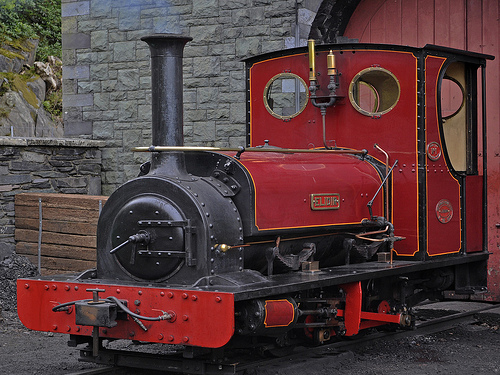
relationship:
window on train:
[267, 75, 308, 115] [16, 34, 496, 373]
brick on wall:
[189, 56, 221, 74] [39, 3, 291, 226]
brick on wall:
[82, 106, 107, 121] [55, 2, 322, 156]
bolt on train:
[214, 297, 221, 303] [16, 34, 496, 373]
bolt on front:
[179, 311, 189, 323] [18, 279, 234, 347]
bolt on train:
[214, 295, 220, 305] [16, 34, 496, 373]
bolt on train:
[190, 294, 196, 301] [16, 34, 496, 373]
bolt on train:
[181, 292, 188, 300] [16, 34, 496, 373]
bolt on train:
[180, 336, 189, 343] [16, 34, 496, 373]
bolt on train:
[168, 334, 176, 344] [16, 34, 496, 373]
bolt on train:
[167, 290, 174, 298] [16, 34, 496, 373]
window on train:
[262, 71, 309, 118] [16, 34, 496, 373]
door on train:
[416, 45, 486, 256] [16, 34, 496, 373]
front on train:
[18, 279, 234, 347] [16, 34, 496, 373]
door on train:
[425, 55, 486, 256] [16, 34, 496, 373]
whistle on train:
[303, 34, 322, 99] [137, 16, 490, 352]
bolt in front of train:
[149, 329, 169, 347] [16, 34, 496, 373]